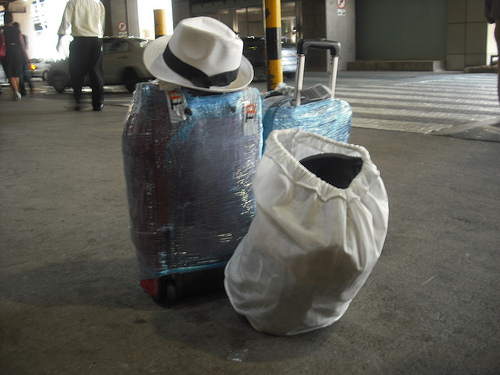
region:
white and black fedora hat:
[140, 13, 256, 96]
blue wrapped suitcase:
[117, 76, 265, 309]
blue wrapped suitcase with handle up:
[262, 39, 354, 150]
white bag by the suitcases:
[218, 126, 391, 339]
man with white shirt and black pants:
[54, 0, 106, 115]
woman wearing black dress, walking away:
[0, 9, 30, 106]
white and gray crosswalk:
[332, 73, 499, 135]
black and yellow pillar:
[258, 1, 285, 91]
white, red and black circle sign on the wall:
[334, 1, 349, 18]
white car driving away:
[38, 34, 160, 94]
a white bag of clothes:
[206, 119, 395, 337]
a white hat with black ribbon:
[128, 9, 255, 98]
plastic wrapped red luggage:
[117, 76, 260, 308]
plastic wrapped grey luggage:
[254, 39, 360, 151]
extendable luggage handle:
[284, 34, 346, 113]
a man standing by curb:
[50, 0, 115, 114]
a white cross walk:
[331, 64, 496, 137]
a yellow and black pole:
[264, 0, 287, 95]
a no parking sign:
[331, 0, 351, 16]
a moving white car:
[36, 32, 160, 94]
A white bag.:
[210, 120, 397, 342]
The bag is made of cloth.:
[190, 120, 397, 338]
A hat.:
[128, 6, 260, 107]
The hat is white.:
[138, 12, 258, 102]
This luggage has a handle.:
[276, 18, 356, 120]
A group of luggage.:
[111, 71, 374, 309]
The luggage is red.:
[103, 71, 380, 305]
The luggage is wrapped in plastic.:
[112, 77, 384, 314]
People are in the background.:
[1, 0, 118, 118]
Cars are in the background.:
[0, 28, 172, 103]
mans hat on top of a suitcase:
[150, 33, 266, 94]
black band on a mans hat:
[161, 46, 200, 79]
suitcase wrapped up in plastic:
[140, 86, 234, 299]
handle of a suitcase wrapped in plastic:
[288, 32, 367, 111]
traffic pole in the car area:
[269, 17, 290, 78]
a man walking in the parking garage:
[61, 3, 111, 114]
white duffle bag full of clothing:
[251, 125, 379, 350]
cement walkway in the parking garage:
[19, 118, 105, 302]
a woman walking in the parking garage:
[3, 13, 42, 111]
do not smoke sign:
[332, 1, 362, 17]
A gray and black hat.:
[140, 14, 254, 90]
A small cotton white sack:
[225, 126, 392, 334]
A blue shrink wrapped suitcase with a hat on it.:
[117, 79, 263, 279]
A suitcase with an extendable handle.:
[261, 36, 351, 156]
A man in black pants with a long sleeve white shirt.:
[54, 0, 109, 112]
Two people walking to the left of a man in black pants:
[0, 11, 40, 100]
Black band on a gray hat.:
[162, 43, 242, 90]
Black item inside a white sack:
[296, 150, 363, 189]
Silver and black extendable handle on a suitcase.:
[293, 38, 340, 108]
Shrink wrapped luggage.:
[120, 80, 351, 304]